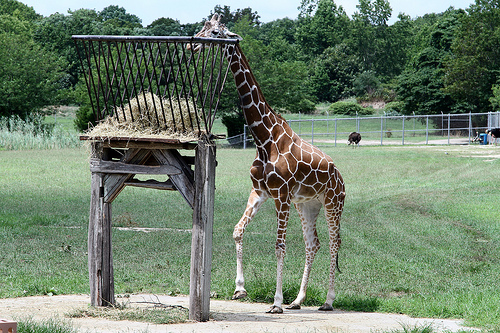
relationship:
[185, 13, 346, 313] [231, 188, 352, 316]
giraffe has legs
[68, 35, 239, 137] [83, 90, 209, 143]
container holds hay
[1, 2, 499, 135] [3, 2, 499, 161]
trees in background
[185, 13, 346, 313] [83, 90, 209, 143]
giraffe reaching for hay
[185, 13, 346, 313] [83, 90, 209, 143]
giraffe trying to eat hay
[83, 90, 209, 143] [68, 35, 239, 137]
hay inside of container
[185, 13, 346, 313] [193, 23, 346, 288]
giraffe has spots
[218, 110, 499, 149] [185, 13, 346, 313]
fence behind giraffe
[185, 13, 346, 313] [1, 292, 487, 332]
giraffe standing on dirt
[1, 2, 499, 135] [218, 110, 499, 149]
trees are behind fence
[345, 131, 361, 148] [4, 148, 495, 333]
ostrich pecking at grass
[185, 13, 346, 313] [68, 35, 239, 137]
giraffe eating from container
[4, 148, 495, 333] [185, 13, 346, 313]
grass around giraffe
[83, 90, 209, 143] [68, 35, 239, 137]
hay in container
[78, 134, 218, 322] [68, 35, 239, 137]
support for container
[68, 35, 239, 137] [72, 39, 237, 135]
container has bars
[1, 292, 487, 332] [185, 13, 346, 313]
dirt near giraffe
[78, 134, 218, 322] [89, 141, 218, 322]
support has legs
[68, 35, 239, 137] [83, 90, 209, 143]
container contains hay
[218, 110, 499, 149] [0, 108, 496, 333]
fence surrounds enclosure